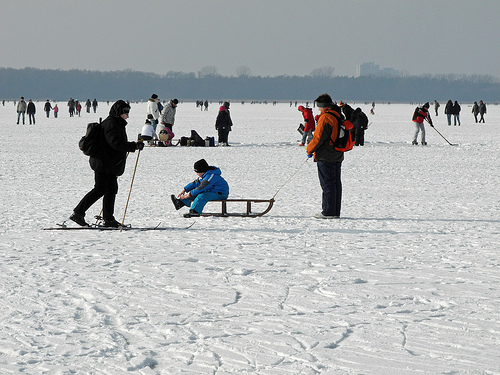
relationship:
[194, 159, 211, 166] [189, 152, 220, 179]
black hat on head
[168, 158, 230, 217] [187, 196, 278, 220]
boy on a sled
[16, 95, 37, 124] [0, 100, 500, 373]
couple walking on snow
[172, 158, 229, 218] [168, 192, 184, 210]
boy fixing shoe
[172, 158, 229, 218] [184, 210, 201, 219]
boy fixing shoe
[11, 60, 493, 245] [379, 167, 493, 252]
people walking on snow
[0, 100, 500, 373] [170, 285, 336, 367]
snow has cracks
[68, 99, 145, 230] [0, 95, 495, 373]
people has skies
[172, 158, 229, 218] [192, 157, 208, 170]
boy has hat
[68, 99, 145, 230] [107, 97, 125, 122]
people has hair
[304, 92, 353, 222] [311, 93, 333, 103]
woman has hair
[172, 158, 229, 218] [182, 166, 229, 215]
boy has coat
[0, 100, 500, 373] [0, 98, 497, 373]
snow on ground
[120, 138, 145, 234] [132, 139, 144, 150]
hockey stick in hand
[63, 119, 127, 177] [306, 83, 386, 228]
backpack on man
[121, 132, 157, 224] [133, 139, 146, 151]
hockey stick in hand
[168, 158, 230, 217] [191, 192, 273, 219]
boy on sled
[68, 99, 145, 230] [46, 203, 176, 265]
people on skis